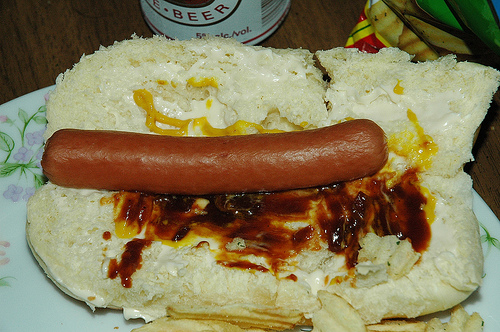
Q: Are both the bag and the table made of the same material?
A: No, the bag is made of plastic and the table is made of wood.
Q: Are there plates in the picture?
A: Yes, there is a plate.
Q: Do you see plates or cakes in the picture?
A: Yes, there is a plate.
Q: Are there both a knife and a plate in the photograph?
A: No, there is a plate but no knives.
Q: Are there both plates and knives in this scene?
A: No, there is a plate but no knives.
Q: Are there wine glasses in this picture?
A: No, there are no wine glasses.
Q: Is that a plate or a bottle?
A: That is a plate.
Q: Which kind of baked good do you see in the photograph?
A: The baked good is a bun.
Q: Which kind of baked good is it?
A: The food is a bun.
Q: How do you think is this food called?
A: This is a bun.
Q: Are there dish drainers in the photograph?
A: No, there are no dish drainers.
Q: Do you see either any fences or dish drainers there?
A: No, there are no dish drainers or fences.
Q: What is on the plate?
A: The flowers are on the plate.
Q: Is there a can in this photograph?
A: Yes, there is a can.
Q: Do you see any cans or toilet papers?
A: Yes, there is a can.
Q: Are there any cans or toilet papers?
A: Yes, there is a can.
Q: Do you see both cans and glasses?
A: No, there is a can but no glasses.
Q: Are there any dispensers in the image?
A: No, there are no dispensers.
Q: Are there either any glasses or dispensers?
A: No, there are no dispensers or glasses.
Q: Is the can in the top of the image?
A: Yes, the can is in the top of the image.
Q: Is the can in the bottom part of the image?
A: No, the can is in the top of the image.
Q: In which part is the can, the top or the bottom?
A: The can is in the top of the image.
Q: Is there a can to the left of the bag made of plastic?
A: Yes, there is a can to the left of the bag.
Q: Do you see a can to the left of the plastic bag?
A: Yes, there is a can to the left of the bag.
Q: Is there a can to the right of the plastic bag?
A: No, the can is to the left of the bag.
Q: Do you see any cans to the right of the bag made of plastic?
A: No, the can is to the left of the bag.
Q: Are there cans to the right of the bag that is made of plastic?
A: No, the can is to the left of the bag.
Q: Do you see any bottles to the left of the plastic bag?
A: No, there is a can to the left of the bag.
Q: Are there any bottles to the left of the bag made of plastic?
A: No, there is a can to the left of the bag.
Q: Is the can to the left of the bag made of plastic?
A: Yes, the can is to the left of the bag.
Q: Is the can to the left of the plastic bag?
A: Yes, the can is to the left of the bag.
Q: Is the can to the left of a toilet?
A: No, the can is to the left of the bag.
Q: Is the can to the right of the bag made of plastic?
A: No, the can is to the left of the bag.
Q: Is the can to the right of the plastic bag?
A: No, the can is to the left of the bag.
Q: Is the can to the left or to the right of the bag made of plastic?
A: The can is to the left of the bag.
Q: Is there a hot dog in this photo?
A: Yes, there is a hot dog.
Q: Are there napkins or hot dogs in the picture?
A: Yes, there is a hot dog.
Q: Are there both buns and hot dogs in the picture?
A: Yes, there are both a hot dog and a bun.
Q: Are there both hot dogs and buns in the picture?
A: Yes, there are both a hot dog and a bun.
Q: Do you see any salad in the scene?
A: No, there is no salad.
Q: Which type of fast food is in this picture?
A: The fast food is a hot dog.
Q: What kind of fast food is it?
A: The food is a hot dog.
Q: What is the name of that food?
A: This is a hot dog.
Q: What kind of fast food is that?
A: This is a hot dog.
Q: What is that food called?
A: This is a hot dog.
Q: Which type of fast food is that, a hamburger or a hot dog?
A: This is a hot dog.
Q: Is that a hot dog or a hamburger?
A: That is a hot dog.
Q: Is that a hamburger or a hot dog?
A: That is a hot dog.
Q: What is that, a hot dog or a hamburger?
A: That is a hot dog.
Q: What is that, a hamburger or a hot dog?
A: That is a hot dog.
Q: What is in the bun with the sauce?
A: The hot dog is in the bun.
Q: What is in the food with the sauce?
A: The hot dog is in the bun.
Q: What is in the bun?
A: The hot dog is in the bun.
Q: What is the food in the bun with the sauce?
A: The food is a hot dog.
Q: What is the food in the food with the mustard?
A: The food is a hot dog.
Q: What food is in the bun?
A: The food is a hot dog.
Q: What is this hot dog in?
A: The hot dog is in the bun.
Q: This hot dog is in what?
A: The hot dog is in the bun.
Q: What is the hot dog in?
A: The hot dog is in the bun.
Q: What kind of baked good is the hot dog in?
A: The hot dog is in the bun.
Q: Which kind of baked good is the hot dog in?
A: The hot dog is in the bun.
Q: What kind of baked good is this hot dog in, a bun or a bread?
A: The hot dog is in a bun.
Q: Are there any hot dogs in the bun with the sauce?
A: Yes, there is a hot dog in the bun.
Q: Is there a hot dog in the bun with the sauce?
A: Yes, there is a hot dog in the bun.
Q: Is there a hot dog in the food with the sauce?
A: Yes, there is a hot dog in the bun.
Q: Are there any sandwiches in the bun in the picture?
A: No, there is a hot dog in the bun.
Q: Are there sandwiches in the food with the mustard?
A: No, there is a hot dog in the bun.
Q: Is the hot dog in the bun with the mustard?
A: Yes, the hot dog is in the bun.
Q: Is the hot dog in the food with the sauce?
A: Yes, the hot dog is in the bun.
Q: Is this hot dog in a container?
A: No, the hot dog is in the bun.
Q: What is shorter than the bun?
A: The hot dog is shorter than the bun.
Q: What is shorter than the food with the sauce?
A: The hot dog is shorter than the bun.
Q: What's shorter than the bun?
A: The hot dog is shorter than the bun.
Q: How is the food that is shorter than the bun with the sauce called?
A: The food is a hot dog.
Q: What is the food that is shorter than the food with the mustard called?
A: The food is a hot dog.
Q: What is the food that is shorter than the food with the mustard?
A: The food is a hot dog.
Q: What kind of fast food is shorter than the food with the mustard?
A: The food is a hot dog.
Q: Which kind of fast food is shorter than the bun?
A: The food is a hot dog.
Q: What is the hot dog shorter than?
A: The hot dog is shorter than the bun.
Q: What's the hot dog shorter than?
A: The hot dog is shorter than the bun.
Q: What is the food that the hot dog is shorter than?
A: The food is a bun.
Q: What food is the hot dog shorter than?
A: The hot dog is shorter than the bun.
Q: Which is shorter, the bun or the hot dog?
A: The hot dog is shorter than the bun.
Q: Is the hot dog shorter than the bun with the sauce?
A: Yes, the hot dog is shorter than the bun.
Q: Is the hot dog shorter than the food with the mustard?
A: Yes, the hot dog is shorter than the bun.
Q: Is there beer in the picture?
A: Yes, there is beer.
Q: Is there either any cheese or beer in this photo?
A: Yes, there is beer.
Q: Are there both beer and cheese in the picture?
A: No, there is beer but no cheese.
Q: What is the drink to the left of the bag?
A: The drink is beer.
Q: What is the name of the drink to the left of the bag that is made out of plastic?
A: The drink is beer.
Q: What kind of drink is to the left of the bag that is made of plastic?
A: The drink is beer.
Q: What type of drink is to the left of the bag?
A: The drink is beer.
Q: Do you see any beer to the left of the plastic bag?
A: Yes, there is beer to the left of the bag.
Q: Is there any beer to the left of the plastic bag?
A: Yes, there is beer to the left of the bag.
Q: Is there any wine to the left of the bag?
A: No, there is beer to the left of the bag.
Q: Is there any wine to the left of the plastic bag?
A: No, there is beer to the left of the bag.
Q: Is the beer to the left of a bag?
A: Yes, the beer is to the left of a bag.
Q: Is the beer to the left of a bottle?
A: No, the beer is to the left of a bag.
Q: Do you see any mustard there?
A: Yes, there is mustard.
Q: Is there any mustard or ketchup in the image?
A: Yes, there is mustard.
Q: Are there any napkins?
A: No, there are no napkins.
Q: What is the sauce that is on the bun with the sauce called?
A: The sauce is mustard.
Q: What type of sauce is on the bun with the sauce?
A: The sauce is mustard.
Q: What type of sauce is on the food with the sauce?
A: The sauce is mustard.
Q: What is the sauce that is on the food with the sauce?
A: The sauce is mustard.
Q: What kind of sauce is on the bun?
A: The sauce is mustard.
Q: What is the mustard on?
A: The mustard is on the bun.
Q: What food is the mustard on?
A: The mustard is on the bun.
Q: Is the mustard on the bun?
A: Yes, the mustard is on the bun.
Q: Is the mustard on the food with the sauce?
A: Yes, the mustard is on the bun.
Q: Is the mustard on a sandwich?
A: No, the mustard is on the bun.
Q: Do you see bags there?
A: Yes, there is a bag.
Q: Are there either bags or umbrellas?
A: Yes, there is a bag.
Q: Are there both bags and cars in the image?
A: No, there is a bag but no cars.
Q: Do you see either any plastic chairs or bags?
A: Yes, there is a plastic bag.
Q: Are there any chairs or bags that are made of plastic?
A: Yes, the bag is made of plastic.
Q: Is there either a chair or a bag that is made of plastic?
A: Yes, the bag is made of plastic.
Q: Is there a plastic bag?
A: Yes, there is a bag that is made of plastic.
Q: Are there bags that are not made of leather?
A: Yes, there is a bag that is made of plastic.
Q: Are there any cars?
A: No, there are no cars.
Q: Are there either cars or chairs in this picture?
A: No, there are no cars or chairs.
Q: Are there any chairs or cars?
A: No, there are no cars or chairs.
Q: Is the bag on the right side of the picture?
A: Yes, the bag is on the right of the image.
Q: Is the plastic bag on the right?
A: Yes, the bag is on the right of the image.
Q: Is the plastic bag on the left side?
A: No, the bag is on the right of the image.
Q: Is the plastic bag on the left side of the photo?
A: No, the bag is on the right of the image.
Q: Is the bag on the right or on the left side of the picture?
A: The bag is on the right of the image.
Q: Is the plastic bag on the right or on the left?
A: The bag is on the right of the image.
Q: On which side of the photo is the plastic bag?
A: The bag is on the right of the image.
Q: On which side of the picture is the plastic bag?
A: The bag is on the right of the image.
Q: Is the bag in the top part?
A: Yes, the bag is in the top of the image.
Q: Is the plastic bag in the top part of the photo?
A: Yes, the bag is in the top of the image.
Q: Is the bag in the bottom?
A: No, the bag is in the top of the image.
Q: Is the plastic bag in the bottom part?
A: No, the bag is in the top of the image.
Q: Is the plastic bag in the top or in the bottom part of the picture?
A: The bag is in the top of the image.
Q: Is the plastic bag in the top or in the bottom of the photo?
A: The bag is in the top of the image.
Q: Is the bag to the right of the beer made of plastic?
A: Yes, the bag is made of plastic.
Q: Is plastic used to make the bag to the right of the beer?
A: Yes, the bag is made of plastic.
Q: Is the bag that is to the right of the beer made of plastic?
A: Yes, the bag is made of plastic.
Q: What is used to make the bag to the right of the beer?
A: The bag is made of plastic.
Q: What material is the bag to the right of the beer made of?
A: The bag is made of plastic.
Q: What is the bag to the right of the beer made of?
A: The bag is made of plastic.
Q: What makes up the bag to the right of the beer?
A: The bag is made of plastic.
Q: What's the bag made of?
A: The bag is made of plastic.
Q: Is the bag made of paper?
A: No, the bag is made of plastic.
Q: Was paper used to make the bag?
A: No, the bag is made of plastic.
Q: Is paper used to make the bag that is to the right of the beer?
A: No, the bag is made of plastic.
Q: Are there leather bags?
A: No, there is a bag but it is made of plastic.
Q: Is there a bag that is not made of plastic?
A: No, there is a bag but it is made of plastic.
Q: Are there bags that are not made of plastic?
A: No, there is a bag but it is made of plastic.